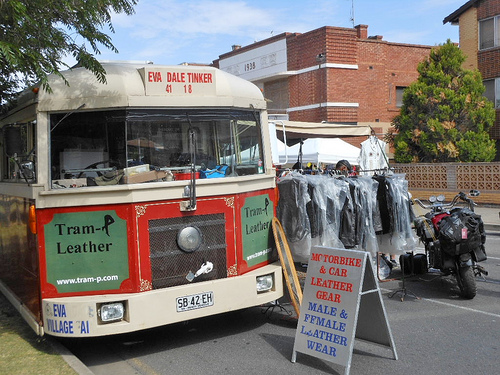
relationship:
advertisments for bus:
[43, 211, 130, 291] [4, 58, 287, 339]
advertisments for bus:
[236, 191, 278, 260] [4, 58, 287, 339]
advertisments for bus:
[289, 242, 387, 362] [4, 58, 287, 339]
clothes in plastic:
[271, 160, 422, 265] [295, 173, 367, 238]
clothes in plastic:
[271, 160, 422, 265] [281, 175, 408, 255]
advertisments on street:
[289, 245, 397, 374] [403, 302, 498, 374]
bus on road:
[4, 58, 287, 339] [82, 227, 492, 370]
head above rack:
[334, 154, 354, 173] [287, 159, 402, 176]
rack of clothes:
[287, 159, 402, 176] [271, 160, 422, 265]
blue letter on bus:
[85, 320, 92, 337] [4, 58, 287, 339]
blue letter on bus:
[78, 314, 86, 336] [4, 58, 287, 339]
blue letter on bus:
[60, 303, 67, 319] [4, 58, 287, 339]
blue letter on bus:
[68, 319, 75, 336] [4, 58, 287, 339]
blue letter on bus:
[53, 317, 63, 334] [4, 58, 287, 339]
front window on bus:
[38, 106, 268, 192] [2, 91, 285, 348]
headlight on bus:
[92, 302, 128, 324] [4, 58, 287, 339]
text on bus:
[143, 70, 215, 93] [4, 58, 287, 339]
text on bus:
[289, 245, 365, 362] [4, 58, 287, 339]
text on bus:
[243, 195, 270, 240] [4, 58, 287, 339]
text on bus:
[49, 213, 119, 288] [4, 58, 287, 339]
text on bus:
[29, 299, 94, 337] [4, 58, 287, 339]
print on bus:
[38, 304, 99, 349] [4, 58, 287, 339]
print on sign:
[310, 249, 360, 306] [294, 247, 401, 373]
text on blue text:
[298, 253, 366, 360] [299, 301, 348, 357]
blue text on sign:
[299, 303, 349, 358] [294, 247, 401, 373]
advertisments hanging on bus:
[43, 209, 130, 293] [4, 58, 287, 339]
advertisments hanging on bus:
[240, 192, 276, 267] [4, 58, 287, 339]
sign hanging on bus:
[147, 67, 215, 94] [4, 58, 287, 339]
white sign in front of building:
[216, 36, 287, 81] [180, 23, 430, 147]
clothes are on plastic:
[271, 160, 422, 265] [278, 165, 407, 257]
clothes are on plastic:
[374, 177, 390, 232] [278, 165, 407, 257]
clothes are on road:
[271, 160, 422, 265] [0, 192, 500, 375]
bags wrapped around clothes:
[282, 168, 411, 258] [281, 176, 409, 244]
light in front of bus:
[255, 269, 277, 294] [4, 58, 287, 339]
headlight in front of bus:
[97, 302, 124, 323] [4, 58, 287, 339]